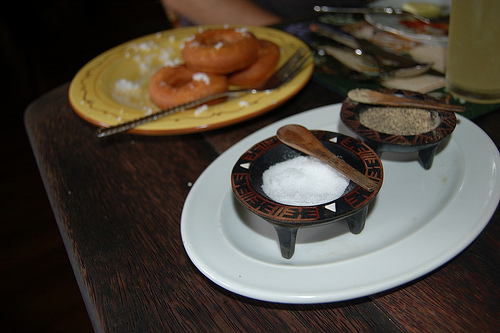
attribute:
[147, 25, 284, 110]
doughnuts — white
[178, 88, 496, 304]
white plate — oval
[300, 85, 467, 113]
spoon — wooden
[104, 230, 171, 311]
table — plates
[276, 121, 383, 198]
spoon — wooden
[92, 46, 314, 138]
fork — silver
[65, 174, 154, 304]
table — brown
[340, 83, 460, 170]
bowl — wooden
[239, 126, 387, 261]
bowl — wooden, brown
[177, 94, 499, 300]
plate — white, oval, yellow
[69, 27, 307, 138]
plate — white, orange, yellow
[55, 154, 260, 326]
table — wooden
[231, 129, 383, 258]
server — round, wooden, salt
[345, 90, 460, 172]
pepper — server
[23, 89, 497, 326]
table — brown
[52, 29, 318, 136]
plate — yellow